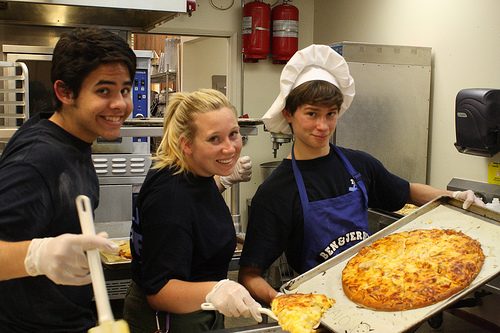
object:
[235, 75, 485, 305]
boy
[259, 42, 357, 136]
hat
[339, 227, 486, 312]
pizza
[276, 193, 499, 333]
tray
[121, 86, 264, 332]
girl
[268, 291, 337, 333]
pizza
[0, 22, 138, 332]
boy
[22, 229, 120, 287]
glove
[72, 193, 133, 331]
spoon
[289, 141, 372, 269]
apron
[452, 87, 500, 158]
dispenser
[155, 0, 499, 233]
wall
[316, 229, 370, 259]
logo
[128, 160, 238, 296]
shirt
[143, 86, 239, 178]
hair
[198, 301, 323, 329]
spatula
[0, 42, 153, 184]
oven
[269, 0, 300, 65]
fire extinguisher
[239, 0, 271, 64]
fire extinguisher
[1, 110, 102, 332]
shirt